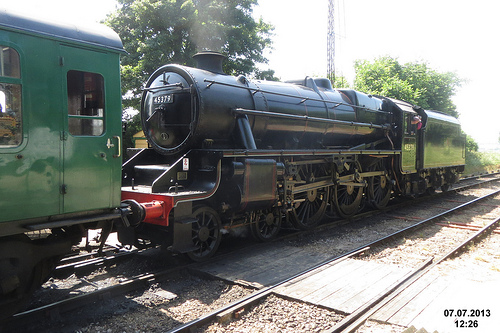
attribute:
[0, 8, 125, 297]
railroad car — green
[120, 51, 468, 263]
locomotive — black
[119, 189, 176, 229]
coupling — red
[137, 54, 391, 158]
engine — black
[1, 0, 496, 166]
background — brightly lit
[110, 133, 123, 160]
door handle — silver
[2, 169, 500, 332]
train track — long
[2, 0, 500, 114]
sky — bright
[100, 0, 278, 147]
tree — green, tall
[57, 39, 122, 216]
door — green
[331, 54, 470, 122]
tree — green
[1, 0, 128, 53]
roof — black